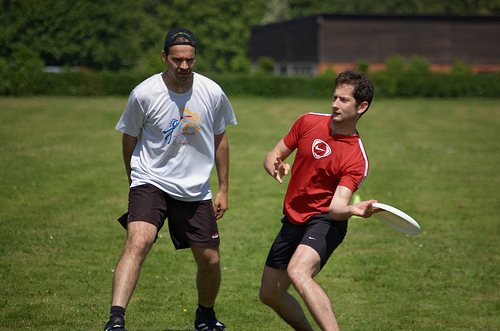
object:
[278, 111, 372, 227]
shirt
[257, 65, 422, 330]
man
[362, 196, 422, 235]
disc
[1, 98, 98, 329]
grass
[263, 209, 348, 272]
shorts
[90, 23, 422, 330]
people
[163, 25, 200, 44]
hat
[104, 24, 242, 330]
person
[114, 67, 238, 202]
top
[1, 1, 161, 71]
trees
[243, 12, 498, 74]
building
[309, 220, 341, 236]
black